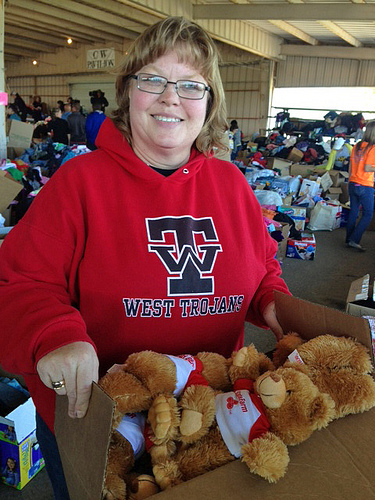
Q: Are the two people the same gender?
A: Yes, all the people are female.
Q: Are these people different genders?
A: No, all the people are female.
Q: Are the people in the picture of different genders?
A: No, all the people are female.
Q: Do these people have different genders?
A: No, all the people are female.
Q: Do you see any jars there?
A: No, there are no jars.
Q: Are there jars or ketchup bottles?
A: No, there are no jars or ketchup bottles.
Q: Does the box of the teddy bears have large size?
A: Yes, the box is large.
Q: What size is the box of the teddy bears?
A: The box is large.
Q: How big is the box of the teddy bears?
A: The box is large.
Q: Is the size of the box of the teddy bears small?
A: No, the box is large.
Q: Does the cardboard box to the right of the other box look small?
A: No, the box is large.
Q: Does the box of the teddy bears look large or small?
A: The box is large.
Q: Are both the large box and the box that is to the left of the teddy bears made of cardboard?
A: Yes, both the box and the box are made of cardboard.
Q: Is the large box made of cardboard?
A: Yes, the box is made of cardboard.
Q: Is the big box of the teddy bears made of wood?
A: No, the box is made of cardboard.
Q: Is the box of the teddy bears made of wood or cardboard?
A: The box is made of cardboard.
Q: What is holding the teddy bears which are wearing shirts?
A: The box is holding the teddy bears.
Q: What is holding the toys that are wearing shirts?
A: The box is holding the teddy bears.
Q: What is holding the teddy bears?
A: The box is holding the teddy bears.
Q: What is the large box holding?
A: The box is holding the teddy bears.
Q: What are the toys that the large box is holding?
A: The toys are teddy bears.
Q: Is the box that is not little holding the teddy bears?
A: Yes, the box is holding the teddy bears.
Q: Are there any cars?
A: No, there are no cars.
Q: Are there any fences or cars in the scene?
A: No, there are no cars or fences.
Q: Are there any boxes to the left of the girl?
A: Yes, there is a box to the left of the girl.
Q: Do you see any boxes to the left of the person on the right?
A: Yes, there is a box to the left of the girl.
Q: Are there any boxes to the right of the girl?
A: No, the box is to the left of the girl.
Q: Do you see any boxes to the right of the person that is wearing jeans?
A: No, the box is to the left of the girl.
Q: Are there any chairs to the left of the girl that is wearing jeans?
A: No, there is a box to the left of the girl.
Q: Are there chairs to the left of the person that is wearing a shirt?
A: No, there is a box to the left of the girl.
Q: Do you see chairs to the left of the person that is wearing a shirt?
A: No, there is a box to the left of the girl.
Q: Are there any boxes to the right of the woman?
A: Yes, there is a box to the right of the woman.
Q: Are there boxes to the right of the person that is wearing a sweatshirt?
A: Yes, there is a box to the right of the woman.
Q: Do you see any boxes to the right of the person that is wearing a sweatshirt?
A: Yes, there is a box to the right of the woman.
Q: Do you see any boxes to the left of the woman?
A: No, the box is to the right of the woman.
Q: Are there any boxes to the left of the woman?
A: No, the box is to the right of the woman.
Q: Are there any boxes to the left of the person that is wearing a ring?
A: No, the box is to the right of the woman.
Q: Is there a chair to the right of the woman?
A: No, there is a box to the right of the woman.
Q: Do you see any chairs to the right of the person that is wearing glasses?
A: No, there is a box to the right of the woman.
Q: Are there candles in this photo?
A: No, there are no candles.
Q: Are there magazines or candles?
A: No, there are no candles or magazines.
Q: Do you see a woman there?
A: Yes, there is a woman.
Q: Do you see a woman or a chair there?
A: Yes, there is a woman.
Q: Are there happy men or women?
A: Yes, there is a happy woman.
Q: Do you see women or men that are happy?
A: Yes, the woman is happy.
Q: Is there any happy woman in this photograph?
A: Yes, there is a happy woman.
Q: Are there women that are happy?
A: Yes, there is a woman that is happy.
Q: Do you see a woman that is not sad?
A: Yes, there is a happy woman.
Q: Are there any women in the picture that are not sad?
A: Yes, there is a happy woman.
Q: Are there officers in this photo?
A: No, there are no officers.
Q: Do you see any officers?
A: No, there are no officers.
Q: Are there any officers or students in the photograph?
A: No, there are no officers or students.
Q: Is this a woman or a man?
A: This is a woman.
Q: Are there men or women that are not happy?
A: No, there is a woman but she is happy.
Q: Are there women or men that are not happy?
A: No, there is a woman but she is happy.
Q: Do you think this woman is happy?
A: Yes, the woman is happy.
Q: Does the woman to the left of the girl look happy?
A: Yes, the woman is happy.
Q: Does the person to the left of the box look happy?
A: Yes, the woman is happy.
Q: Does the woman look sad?
A: No, the woman is happy.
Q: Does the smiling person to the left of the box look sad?
A: No, the woman is happy.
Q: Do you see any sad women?
A: No, there is a woman but she is happy.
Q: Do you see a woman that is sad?
A: No, there is a woman but she is happy.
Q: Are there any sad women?
A: No, there is a woman but she is happy.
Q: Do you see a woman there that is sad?
A: No, there is a woman but she is happy.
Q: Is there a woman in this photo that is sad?
A: No, there is a woman but she is happy.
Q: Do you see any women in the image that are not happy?
A: No, there is a woman but she is happy.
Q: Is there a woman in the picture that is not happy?
A: No, there is a woman but she is happy.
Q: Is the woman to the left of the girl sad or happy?
A: The woman is happy.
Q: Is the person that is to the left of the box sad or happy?
A: The woman is happy.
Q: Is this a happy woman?
A: Yes, this is a happy woman.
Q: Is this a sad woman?
A: No, this is a happy woman.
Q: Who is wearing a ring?
A: The woman is wearing a ring.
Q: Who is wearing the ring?
A: The woman is wearing a ring.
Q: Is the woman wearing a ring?
A: Yes, the woman is wearing a ring.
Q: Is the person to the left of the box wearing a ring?
A: Yes, the woman is wearing a ring.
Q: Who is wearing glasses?
A: The woman is wearing glasses.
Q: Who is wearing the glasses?
A: The woman is wearing glasses.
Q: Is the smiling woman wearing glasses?
A: Yes, the woman is wearing glasses.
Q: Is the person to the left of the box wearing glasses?
A: Yes, the woman is wearing glasses.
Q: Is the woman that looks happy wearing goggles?
A: No, the woman is wearing glasses.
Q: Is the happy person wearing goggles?
A: No, the woman is wearing glasses.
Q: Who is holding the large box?
A: The woman is holding the box.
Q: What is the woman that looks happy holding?
A: The woman is holding the box.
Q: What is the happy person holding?
A: The woman is holding the box.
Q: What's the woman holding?
A: The woman is holding the box.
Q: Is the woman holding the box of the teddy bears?
A: Yes, the woman is holding the box.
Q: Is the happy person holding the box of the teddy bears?
A: Yes, the woman is holding the box.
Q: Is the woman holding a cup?
A: No, the woman is holding the box.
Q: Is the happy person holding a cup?
A: No, the woman is holding the box.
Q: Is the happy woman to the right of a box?
A: No, the woman is to the left of a box.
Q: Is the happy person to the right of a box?
A: No, the woman is to the left of a box.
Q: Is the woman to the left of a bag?
A: No, the woman is to the left of the box.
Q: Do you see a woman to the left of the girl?
A: Yes, there is a woman to the left of the girl.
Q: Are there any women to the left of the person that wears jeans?
A: Yes, there is a woman to the left of the girl.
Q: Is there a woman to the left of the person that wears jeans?
A: Yes, there is a woman to the left of the girl.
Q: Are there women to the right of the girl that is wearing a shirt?
A: No, the woman is to the left of the girl.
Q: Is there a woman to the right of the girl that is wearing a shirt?
A: No, the woman is to the left of the girl.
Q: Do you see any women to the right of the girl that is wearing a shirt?
A: No, the woman is to the left of the girl.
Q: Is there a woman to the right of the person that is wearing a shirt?
A: No, the woman is to the left of the girl.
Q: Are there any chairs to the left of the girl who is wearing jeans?
A: No, there is a woman to the left of the girl.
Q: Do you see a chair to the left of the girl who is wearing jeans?
A: No, there is a woman to the left of the girl.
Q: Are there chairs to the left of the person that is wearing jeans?
A: No, there is a woman to the left of the girl.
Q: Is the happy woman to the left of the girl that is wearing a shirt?
A: Yes, the woman is to the left of the girl.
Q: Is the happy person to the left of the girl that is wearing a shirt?
A: Yes, the woman is to the left of the girl.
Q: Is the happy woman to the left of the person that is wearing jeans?
A: Yes, the woman is to the left of the girl.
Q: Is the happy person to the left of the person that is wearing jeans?
A: Yes, the woman is to the left of the girl.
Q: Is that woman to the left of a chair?
A: No, the woman is to the left of the girl.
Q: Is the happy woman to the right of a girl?
A: No, the woman is to the left of a girl.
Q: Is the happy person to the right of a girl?
A: No, the woman is to the left of a girl.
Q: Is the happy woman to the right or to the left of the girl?
A: The woman is to the left of the girl.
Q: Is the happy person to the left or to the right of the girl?
A: The woman is to the left of the girl.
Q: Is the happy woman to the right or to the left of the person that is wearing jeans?
A: The woman is to the left of the girl.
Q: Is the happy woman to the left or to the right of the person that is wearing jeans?
A: The woman is to the left of the girl.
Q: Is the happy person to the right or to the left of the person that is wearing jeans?
A: The woman is to the left of the girl.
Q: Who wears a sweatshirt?
A: The woman wears a sweatshirt.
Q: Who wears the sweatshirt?
A: The woman wears a sweatshirt.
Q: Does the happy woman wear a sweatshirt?
A: Yes, the woman wears a sweatshirt.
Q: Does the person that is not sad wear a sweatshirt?
A: Yes, the woman wears a sweatshirt.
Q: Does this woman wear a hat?
A: No, the woman wears a sweatshirt.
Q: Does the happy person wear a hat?
A: No, the woman wears a sweatshirt.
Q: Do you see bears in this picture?
A: Yes, there is a bear.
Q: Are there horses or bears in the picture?
A: Yes, there is a bear.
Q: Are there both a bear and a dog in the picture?
A: No, there is a bear but no dogs.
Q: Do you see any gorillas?
A: No, there are no gorillas.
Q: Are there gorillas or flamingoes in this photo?
A: No, there are no gorillas or flamingoes.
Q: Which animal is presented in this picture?
A: The animal is a bear.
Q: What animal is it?
A: The animal is a bear.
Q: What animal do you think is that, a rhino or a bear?
A: This is a bear.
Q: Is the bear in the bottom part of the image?
A: Yes, the bear is in the bottom of the image.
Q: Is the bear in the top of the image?
A: No, the bear is in the bottom of the image.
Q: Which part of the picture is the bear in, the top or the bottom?
A: The bear is in the bottom of the image.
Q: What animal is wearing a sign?
A: The bear is wearing a sign.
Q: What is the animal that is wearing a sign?
A: The animal is a bear.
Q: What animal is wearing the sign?
A: The animal is a bear.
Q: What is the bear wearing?
A: The bear is wearing a sign.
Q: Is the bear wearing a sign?
A: Yes, the bear is wearing a sign.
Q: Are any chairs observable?
A: No, there are no chairs.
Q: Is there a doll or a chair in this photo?
A: No, there are no chairs or dolls.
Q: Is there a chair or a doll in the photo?
A: No, there are no chairs or dolls.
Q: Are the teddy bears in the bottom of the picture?
A: Yes, the teddy bears are in the bottom of the image.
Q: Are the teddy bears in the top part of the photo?
A: No, the teddy bears are in the bottom of the image.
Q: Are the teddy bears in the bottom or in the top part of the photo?
A: The teddy bears are in the bottom of the image.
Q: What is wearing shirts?
A: The teddy bears are wearing shirts.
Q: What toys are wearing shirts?
A: The toys are teddy bears.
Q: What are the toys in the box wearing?
A: The teddy bears are wearing shirts.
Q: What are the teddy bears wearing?
A: The teddy bears are wearing shirts.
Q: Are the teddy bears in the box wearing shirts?
A: Yes, the teddy bears are wearing shirts.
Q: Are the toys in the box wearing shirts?
A: Yes, the teddy bears are wearing shirts.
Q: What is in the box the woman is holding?
A: The teddy bears are in the box.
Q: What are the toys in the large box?
A: The toys are teddy bears.